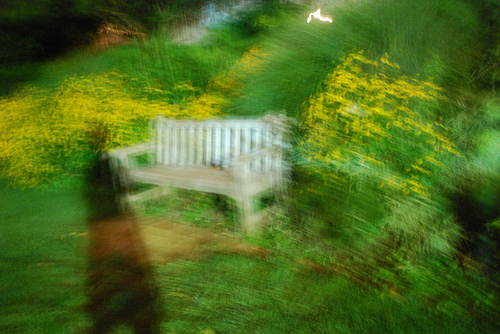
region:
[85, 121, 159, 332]
A shadow of a person on the grass.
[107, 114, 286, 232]
A white and tan bench.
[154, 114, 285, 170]
White back slats of a bench.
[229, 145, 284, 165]
The right side arm of a bench.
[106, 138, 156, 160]
Left arm of a bench.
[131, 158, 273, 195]
Tan seat of a bench.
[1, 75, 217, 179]
Yellow group of flowers where the shadow of a person is.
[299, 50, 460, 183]
A yellow group of flowers to the back right of a bench.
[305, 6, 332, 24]
A white line in that doesn't belong there in the grass area.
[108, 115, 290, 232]
A white and tan bench in the middle of flowers.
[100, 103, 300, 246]
Small white bench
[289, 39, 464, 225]
Yellow flowers in bush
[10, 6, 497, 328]
Very blurry bench and grass area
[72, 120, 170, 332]
Shadow of person on the ground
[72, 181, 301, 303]
Small pile of dirt next to the bench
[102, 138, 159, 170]
White arm rest on bench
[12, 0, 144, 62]
House in the distance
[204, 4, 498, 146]
Tall green grass behind the bench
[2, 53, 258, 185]
Large area of yellow flowers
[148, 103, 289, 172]
White backrest of bench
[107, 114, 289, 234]
A white bench.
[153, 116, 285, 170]
Back white verticle slats of a bench.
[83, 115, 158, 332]
A dark shadow on the ground.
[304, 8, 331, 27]
A zig zagged white line on the top.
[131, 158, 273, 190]
The wood seat of a bench.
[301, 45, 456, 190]
Yellow bunch of flowers to the right of a bench.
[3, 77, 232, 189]
A large group of yellow flowers with a shadow in it.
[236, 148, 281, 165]
Right arm of the white bench.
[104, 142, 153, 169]
Left arm of a white bench.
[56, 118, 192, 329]
A shadow figure in the picture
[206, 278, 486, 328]
The grass is short and green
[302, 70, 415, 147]
The flowers are the color yellow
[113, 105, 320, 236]
The bench is the color white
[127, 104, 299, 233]
The bench is made of wood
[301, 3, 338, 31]
A piece of light in the air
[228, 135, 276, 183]
The arm of the bench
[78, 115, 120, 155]
The head of the figure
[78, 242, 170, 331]
The bottom of the figure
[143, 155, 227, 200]
The seat of the bench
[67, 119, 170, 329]
A person's shadow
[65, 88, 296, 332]
A person's shadow next to a white bench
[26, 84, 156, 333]
A person's shadow next to yellow flowers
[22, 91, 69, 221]
blurry yellow flowers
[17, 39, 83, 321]
blurry yellow flowers in a garden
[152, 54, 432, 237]
blurry yellow flowers next to a white bench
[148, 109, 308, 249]
white bench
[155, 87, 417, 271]
white bench in a flower garden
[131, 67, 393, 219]
Yellow flowers next to a white bench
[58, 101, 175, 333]
A long shadow of a person